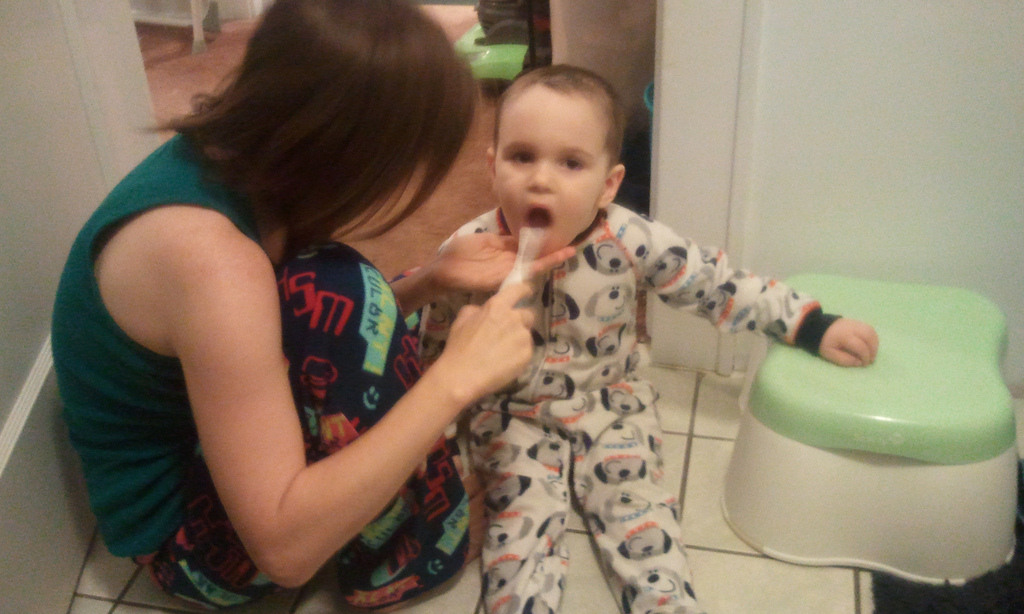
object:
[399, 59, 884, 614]
boy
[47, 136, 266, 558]
shirt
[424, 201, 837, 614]
pajamas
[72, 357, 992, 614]
floor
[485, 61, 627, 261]
head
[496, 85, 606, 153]
forehead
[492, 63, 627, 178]
hair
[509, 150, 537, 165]
eye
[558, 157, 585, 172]
eye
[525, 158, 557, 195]
nose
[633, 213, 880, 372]
arm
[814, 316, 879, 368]
hand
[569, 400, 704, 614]
left leg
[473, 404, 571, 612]
right leg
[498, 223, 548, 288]
brush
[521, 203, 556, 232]
mouth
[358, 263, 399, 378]
patch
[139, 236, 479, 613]
pants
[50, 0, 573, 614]
woman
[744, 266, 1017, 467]
seat cover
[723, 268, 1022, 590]
seat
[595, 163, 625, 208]
left ear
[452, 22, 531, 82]
paper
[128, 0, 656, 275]
background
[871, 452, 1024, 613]
carpet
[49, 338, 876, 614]
tile